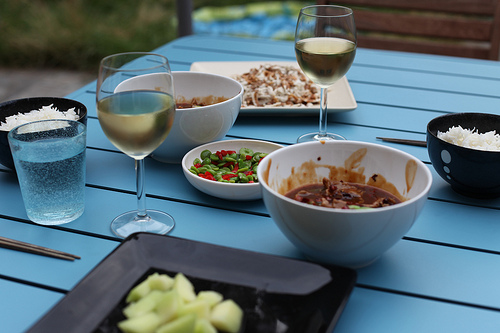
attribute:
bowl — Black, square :
[29, 228, 359, 322]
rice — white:
[2, 99, 82, 130]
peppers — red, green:
[185, 142, 267, 184]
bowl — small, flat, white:
[176, 134, 283, 202]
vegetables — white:
[192, 148, 264, 182]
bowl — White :
[112, 69, 247, 158]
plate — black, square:
[106, 226, 318, 328]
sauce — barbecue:
[366, 180, 398, 207]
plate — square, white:
[190, 57, 360, 117]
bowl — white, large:
[239, 105, 452, 267]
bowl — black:
[425, 110, 499, 202]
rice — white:
[435, 125, 499, 150]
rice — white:
[1, 102, 78, 129]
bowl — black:
[3, 96, 89, 176]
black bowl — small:
[419, 112, 499, 198]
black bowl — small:
[0, 93, 88, 171]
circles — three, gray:
[439, 146, 454, 184]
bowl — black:
[422, 106, 499, 196]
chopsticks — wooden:
[0, 239, 82, 262]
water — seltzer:
[10, 150, 86, 220]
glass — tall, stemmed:
[285, 0, 352, 137]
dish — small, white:
[181, 138, 281, 201]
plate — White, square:
[165, 47, 355, 229]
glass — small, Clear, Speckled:
[6, 118, 86, 228]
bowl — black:
[0, 95, 91, 181]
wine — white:
[95, 90, 172, 160]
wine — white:
[293, 36, 356, 87]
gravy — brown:
[284, 173, 404, 211]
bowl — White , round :
[112, 68, 241, 169]